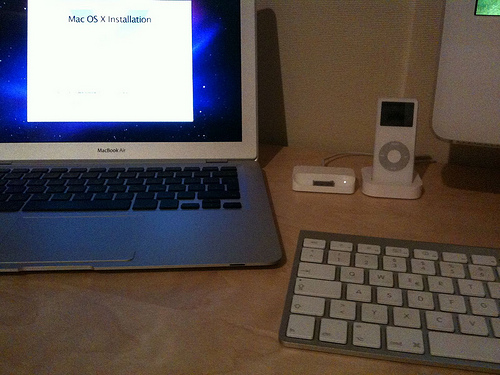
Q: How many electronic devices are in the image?
A: Two.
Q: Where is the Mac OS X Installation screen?
A: On the laptop.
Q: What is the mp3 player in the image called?
A: An iPod.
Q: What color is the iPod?
A: White.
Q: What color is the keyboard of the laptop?
A: Black.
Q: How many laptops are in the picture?
A: One.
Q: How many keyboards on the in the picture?
A: Two.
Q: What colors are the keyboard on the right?
A: White and gray.